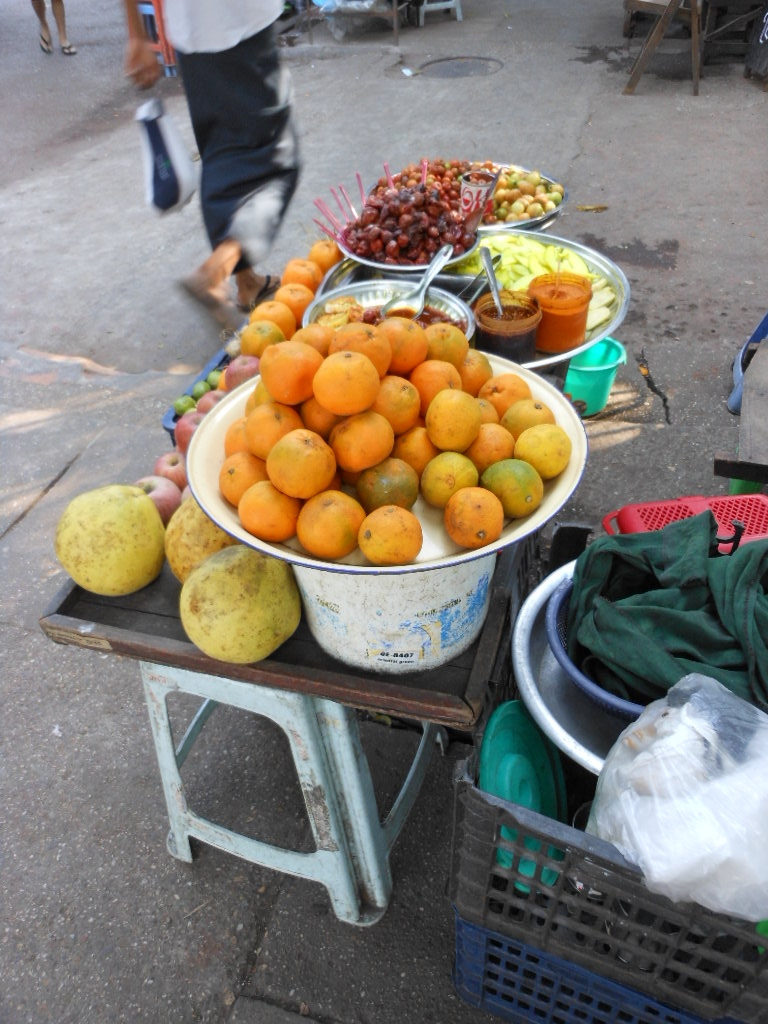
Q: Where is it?
A: This is at the pavement.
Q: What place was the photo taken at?
A: It was taken at the pavement.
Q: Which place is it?
A: It is a pavement.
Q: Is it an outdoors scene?
A: Yes, it is outdoors.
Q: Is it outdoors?
A: Yes, it is outdoors.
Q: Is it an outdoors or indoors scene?
A: It is outdoors.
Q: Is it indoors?
A: No, it is outdoors.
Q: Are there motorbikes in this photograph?
A: No, there are no motorbikes.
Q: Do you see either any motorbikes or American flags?
A: No, there are no motorbikes or American flags.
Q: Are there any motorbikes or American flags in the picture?
A: No, there are no motorbikes or American flags.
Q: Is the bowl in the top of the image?
A: Yes, the bowl is in the top of the image.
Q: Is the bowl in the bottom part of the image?
A: No, the bowl is in the top of the image.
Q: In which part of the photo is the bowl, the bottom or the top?
A: The bowl is in the top of the image.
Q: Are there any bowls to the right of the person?
A: Yes, there is a bowl to the right of the person.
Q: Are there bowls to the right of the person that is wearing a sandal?
A: Yes, there is a bowl to the right of the person.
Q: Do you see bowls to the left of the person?
A: No, the bowl is to the right of the person.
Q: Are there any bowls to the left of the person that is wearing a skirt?
A: No, the bowl is to the right of the person.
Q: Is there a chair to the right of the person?
A: No, there is a bowl to the right of the person.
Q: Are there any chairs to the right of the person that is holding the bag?
A: No, there is a bowl to the right of the person.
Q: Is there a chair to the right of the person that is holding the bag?
A: No, there is a bowl to the right of the person.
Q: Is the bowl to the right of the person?
A: Yes, the bowl is to the right of the person.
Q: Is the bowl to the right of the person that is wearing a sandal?
A: Yes, the bowl is to the right of the person.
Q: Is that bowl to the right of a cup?
A: No, the bowl is to the right of the person.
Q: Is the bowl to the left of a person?
A: No, the bowl is to the right of a person.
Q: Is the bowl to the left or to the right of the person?
A: The bowl is to the right of the person.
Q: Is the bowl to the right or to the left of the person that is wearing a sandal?
A: The bowl is to the right of the person.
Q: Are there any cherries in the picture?
A: Yes, there are cherries.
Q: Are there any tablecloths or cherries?
A: Yes, there are cherries.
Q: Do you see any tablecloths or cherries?
A: Yes, there are cherries.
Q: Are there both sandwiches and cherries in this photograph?
A: No, there are cherries but no sandwiches.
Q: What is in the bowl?
A: The cherries are in the bowl.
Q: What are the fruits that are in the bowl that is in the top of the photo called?
A: The fruits are cherries.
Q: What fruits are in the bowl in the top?
A: The fruits are cherries.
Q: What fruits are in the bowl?
A: The fruits are cherries.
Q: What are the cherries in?
A: The cherries are in the bowl.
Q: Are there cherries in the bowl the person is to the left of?
A: Yes, there are cherries in the bowl.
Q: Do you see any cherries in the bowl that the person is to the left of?
A: Yes, there are cherries in the bowl.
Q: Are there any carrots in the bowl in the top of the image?
A: No, there are cherries in the bowl.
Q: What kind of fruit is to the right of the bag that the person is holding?
A: The fruits are cherries.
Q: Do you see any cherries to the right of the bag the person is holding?
A: Yes, there are cherries to the right of the bag.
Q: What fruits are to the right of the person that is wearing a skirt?
A: The fruits are cherries.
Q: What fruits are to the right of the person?
A: The fruits are cherries.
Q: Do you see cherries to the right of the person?
A: Yes, there are cherries to the right of the person.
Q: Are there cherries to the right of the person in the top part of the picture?
A: Yes, there are cherries to the right of the person.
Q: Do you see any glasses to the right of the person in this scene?
A: No, there are cherries to the right of the person.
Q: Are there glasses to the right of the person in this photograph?
A: No, there are cherries to the right of the person.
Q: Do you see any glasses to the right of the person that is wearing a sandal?
A: No, there are cherries to the right of the person.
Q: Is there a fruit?
A: Yes, there is a fruit.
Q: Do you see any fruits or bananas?
A: Yes, there is a fruit.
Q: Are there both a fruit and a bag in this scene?
A: Yes, there are both a fruit and a bag.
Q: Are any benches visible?
A: Yes, there is a bench.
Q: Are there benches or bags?
A: Yes, there is a bench.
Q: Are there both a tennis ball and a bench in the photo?
A: No, there is a bench but no tennis balls.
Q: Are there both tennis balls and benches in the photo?
A: No, there is a bench but no tennis balls.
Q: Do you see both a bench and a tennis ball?
A: No, there is a bench but no tennis balls.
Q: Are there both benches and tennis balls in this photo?
A: No, there is a bench but no tennis balls.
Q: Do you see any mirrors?
A: No, there are no mirrors.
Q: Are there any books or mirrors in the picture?
A: No, there are no mirrors or books.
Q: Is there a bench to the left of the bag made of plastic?
A: Yes, there is a bench to the left of the bag.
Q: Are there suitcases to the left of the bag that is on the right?
A: No, there is a bench to the left of the bag.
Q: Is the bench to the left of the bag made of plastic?
A: Yes, the bench is to the left of the bag.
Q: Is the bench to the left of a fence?
A: No, the bench is to the left of the bag.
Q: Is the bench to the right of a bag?
A: No, the bench is to the left of a bag.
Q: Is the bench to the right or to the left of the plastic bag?
A: The bench is to the left of the bag.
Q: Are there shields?
A: No, there are no shields.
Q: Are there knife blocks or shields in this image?
A: No, there are no shields or knife blocks.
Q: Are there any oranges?
A: Yes, there are oranges.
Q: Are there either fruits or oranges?
A: Yes, there are oranges.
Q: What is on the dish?
A: The oranges are on the dish.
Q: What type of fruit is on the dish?
A: The fruits are oranges.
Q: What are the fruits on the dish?
A: The fruits are oranges.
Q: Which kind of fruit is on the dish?
A: The fruits are oranges.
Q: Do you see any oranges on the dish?
A: Yes, there are oranges on the dish.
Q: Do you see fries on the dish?
A: No, there are oranges on the dish.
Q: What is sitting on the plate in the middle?
A: The oranges are sitting on the plate.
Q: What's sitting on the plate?
A: The oranges are sitting on the plate.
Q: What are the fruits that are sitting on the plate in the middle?
A: The fruits are oranges.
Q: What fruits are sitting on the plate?
A: The fruits are oranges.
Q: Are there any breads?
A: No, there are no breads.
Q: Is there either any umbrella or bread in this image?
A: No, there are no breads or umbrellas.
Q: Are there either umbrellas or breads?
A: No, there are no breads or umbrellas.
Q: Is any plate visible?
A: Yes, there is a plate.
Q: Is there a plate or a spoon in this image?
A: Yes, there is a plate.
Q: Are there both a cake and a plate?
A: No, there is a plate but no cakes.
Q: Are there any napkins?
A: No, there are no napkins.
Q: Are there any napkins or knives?
A: No, there are no napkins or knives.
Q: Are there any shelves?
A: No, there are no shelves.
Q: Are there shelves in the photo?
A: No, there are no shelves.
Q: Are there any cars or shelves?
A: No, there are no shelves or cars.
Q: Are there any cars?
A: No, there are no cars.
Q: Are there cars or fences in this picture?
A: No, there are no cars or fences.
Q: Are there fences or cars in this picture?
A: No, there are no cars or fences.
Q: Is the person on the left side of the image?
A: Yes, the person is on the left of the image.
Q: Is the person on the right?
A: No, the person is on the left of the image.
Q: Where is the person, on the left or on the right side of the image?
A: The person is on the left of the image.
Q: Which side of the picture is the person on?
A: The person is on the left of the image.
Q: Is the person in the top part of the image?
A: Yes, the person is in the top of the image.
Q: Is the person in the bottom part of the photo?
A: No, the person is in the top of the image.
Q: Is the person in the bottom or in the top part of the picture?
A: The person is in the top of the image.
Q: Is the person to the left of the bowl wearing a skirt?
A: Yes, the person is wearing a skirt.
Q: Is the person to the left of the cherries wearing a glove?
A: No, the person is wearing a skirt.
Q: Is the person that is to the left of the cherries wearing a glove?
A: No, the person is wearing a skirt.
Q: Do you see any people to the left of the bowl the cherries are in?
A: Yes, there is a person to the left of the bowl.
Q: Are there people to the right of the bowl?
A: No, the person is to the left of the bowl.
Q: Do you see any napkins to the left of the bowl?
A: No, there is a person to the left of the bowl.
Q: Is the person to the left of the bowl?
A: Yes, the person is to the left of the bowl.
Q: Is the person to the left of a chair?
A: No, the person is to the left of the bowl.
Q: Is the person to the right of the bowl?
A: No, the person is to the left of the bowl.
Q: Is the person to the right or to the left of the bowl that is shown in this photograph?
A: The person is to the left of the bowl.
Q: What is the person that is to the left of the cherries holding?
A: The person is holding the bag.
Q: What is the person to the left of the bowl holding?
A: The person is holding the bag.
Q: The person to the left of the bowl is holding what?
A: The person is holding the bag.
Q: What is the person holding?
A: The person is holding the bag.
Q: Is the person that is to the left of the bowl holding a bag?
A: Yes, the person is holding a bag.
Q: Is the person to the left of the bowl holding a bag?
A: Yes, the person is holding a bag.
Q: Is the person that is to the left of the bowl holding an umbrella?
A: No, the person is holding a bag.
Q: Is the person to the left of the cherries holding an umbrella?
A: No, the person is holding a bag.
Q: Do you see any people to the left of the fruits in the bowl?
A: Yes, there is a person to the left of the cherries.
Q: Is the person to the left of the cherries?
A: Yes, the person is to the left of the cherries.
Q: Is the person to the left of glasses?
A: No, the person is to the left of the cherries.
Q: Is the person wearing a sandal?
A: Yes, the person is wearing a sandal.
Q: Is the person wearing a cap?
A: No, the person is wearing a sandal.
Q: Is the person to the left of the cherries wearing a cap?
A: No, the person is wearing a sandal.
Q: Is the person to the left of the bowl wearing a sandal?
A: Yes, the person is wearing a sandal.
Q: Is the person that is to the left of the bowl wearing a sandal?
A: Yes, the person is wearing a sandal.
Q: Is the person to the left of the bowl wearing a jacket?
A: No, the person is wearing a sandal.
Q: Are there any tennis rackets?
A: No, there are no tennis rackets.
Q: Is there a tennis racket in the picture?
A: No, there are no rackets.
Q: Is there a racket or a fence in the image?
A: No, there are no rackets or fences.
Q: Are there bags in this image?
A: Yes, there is a bag.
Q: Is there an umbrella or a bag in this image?
A: Yes, there is a bag.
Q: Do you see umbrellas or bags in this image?
A: Yes, there is a bag.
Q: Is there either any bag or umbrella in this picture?
A: Yes, there is a bag.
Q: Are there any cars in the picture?
A: No, there are no cars.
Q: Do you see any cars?
A: No, there are no cars.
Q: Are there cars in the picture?
A: No, there are no cars.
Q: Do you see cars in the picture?
A: No, there are no cars.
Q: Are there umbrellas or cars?
A: No, there are no cars or umbrellas.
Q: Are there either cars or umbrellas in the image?
A: No, there are no cars or umbrellas.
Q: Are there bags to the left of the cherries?
A: Yes, there is a bag to the left of the cherries.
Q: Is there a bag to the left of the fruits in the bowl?
A: Yes, there is a bag to the left of the cherries.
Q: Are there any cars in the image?
A: No, there are no cars.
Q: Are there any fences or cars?
A: No, there are no cars or fences.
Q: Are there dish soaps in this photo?
A: No, there are no dish soaps.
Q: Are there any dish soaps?
A: No, there are no dish soaps.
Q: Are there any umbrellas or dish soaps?
A: No, there are no dish soaps or umbrellas.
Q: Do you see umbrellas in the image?
A: No, there are no umbrellas.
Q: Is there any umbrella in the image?
A: No, there are no umbrellas.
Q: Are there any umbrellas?
A: No, there are no umbrellas.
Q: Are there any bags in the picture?
A: Yes, there is a bag.